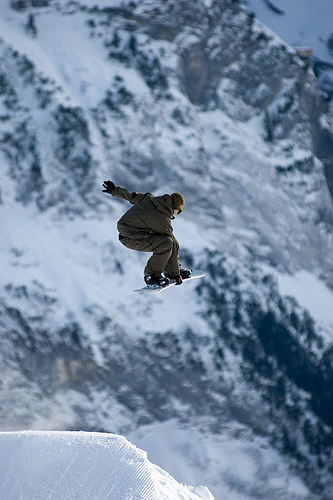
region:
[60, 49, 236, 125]
snow covered mountain range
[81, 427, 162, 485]
marks on top of snow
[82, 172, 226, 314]
skier holding a skate board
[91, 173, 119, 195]
glove on skier's hand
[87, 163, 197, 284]
this is a man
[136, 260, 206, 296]
this is a snowboard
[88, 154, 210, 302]
man on a snowboard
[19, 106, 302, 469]
man high in the air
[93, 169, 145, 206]
man has arm extended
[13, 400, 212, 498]
snow under the man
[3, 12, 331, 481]
mountain scape in the background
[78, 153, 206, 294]
person on board jumping in air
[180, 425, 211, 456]
wwhite snow on hill side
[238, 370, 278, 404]
wwhite snow on hill side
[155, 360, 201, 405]
wwhite snow on hill side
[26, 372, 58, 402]
wwhite snow on hill side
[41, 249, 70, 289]
wwhite snow on hill side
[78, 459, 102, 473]
wwhite snow on hill side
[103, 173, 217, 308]
Person in the air on a snow board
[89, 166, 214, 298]
Person in the air on a snow board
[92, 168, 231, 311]
Person in the air on a snow board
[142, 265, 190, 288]
person wearing black boots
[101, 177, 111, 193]
person wearing black gloves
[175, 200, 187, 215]
person wearing goggles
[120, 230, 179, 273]
person wearing brown pants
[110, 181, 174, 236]
person wearing a brown jacket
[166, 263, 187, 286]
man holding a snowboard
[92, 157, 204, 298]
person doing trick in air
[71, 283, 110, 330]
wwhite snow on hill side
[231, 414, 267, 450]
wwhite snow on hill side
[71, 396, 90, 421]
wwhite snow on hill side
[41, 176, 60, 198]
wwhite snow on hill side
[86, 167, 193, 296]
man doing trick in air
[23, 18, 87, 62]
white clouds in blue sky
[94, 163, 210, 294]
skier flying through the air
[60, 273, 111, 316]
snow on the side of a mountain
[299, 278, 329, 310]
snow on the side of a mountain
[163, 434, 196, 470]
snow on the side of a mountain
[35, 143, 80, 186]
snow on the side of a mountain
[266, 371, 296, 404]
snow on the side of a mountain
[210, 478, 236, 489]
white snow on the side of a mountain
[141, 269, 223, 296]
white snow board on the guys feet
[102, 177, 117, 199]
a black ski glove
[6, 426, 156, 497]
creases in the snow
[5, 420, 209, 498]
a large snow wedge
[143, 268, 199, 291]
two black winter shoes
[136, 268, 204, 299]
a long white snowboard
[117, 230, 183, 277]
a pair of snow pants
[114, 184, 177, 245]
a grey sweater with hoodie